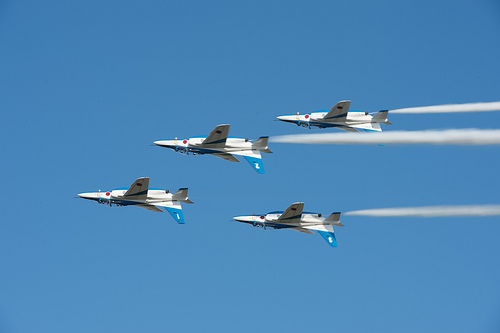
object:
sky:
[0, 0, 498, 331]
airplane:
[74, 176, 195, 225]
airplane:
[230, 202, 345, 249]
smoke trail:
[342, 205, 500, 217]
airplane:
[150, 124, 275, 175]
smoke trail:
[269, 128, 500, 146]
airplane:
[272, 100, 395, 146]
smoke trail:
[368, 101, 500, 113]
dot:
[106, 192, 111, 196]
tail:
[164, 201, 186, 224]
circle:
[137, 183, 143, 187]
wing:
[122, 177, 150, 198]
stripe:
[124, 190, 148, 197]